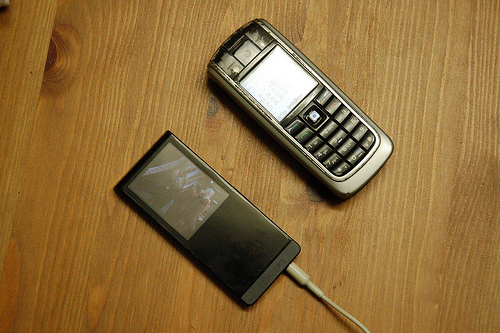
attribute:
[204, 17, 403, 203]
cellphone — old, laying, black, little, small, silver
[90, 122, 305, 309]
ipod — old, on, black, is mini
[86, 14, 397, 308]
electronic devices — black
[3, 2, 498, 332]
table — brown, dark, wooden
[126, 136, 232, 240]
screen — lit, is light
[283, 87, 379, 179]
keyboard — dark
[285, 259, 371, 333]
charger — small, white, grey, light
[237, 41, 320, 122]
screen — white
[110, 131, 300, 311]
ipod — is black